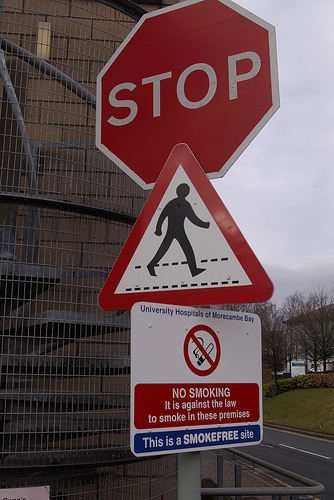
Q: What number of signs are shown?
A: Three.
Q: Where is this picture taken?
A: A street.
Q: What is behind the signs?
A: Staircase.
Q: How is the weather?
A: Overcast.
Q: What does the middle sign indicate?
A: Walking.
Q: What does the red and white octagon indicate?
A: To stop.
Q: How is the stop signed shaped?
A: Like an octagon.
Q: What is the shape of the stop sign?
A: Octagon.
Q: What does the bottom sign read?
A: No smoking.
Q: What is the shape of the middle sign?
A: Triangle.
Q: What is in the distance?
A: A road.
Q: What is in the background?
A: Trees.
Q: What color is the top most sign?
A: Red.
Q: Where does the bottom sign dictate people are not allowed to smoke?
A: University Hospitals of Morecambe Bay,.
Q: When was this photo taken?
A: Day time.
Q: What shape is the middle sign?
A: Triangle.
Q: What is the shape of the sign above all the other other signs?
A: Hexagon.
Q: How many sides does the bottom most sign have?
A: Four.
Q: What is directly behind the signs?
A: A staircase.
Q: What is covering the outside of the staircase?
A: A cage.